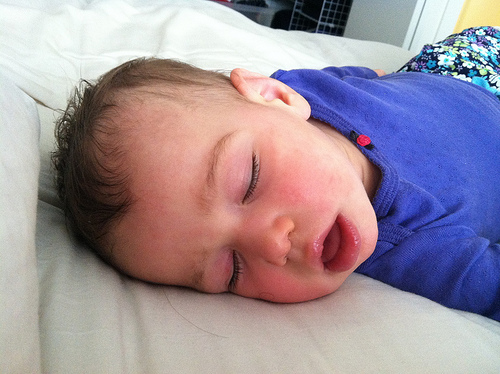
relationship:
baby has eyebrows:
[52, 24, 498, 296] [181, 122, 233, 299]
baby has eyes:
[52, 24, 498, 296] [217, 137, 266, 306]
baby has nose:
[52, 24, 498, 296] [248, 218, 299, 264]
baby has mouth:
[52, 24, 498, 296] [307, 200, 361, 282]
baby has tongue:
[52, 24, 498, 296] [323, 229, 344, 264]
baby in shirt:
[52, 24, 498, 296] [276, 44, 490, 311]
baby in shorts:
[52, 24, 498, 296] [398, 16, 499, 96]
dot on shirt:
[352, 129, 374, 151] [276, 44, 490, 311]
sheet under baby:
[0, 2, 463, 371] [52, 24, 498, 296]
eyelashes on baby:
[230, 149, 261, 302] [52, 24, 498, 296]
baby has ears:
[52, 24, 498, 296] [227, 61, 327, 120]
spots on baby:
[132, 102, 171, 149] [52, 24, 498, 296]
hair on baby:
[50, 50, 183, 274] [52, 24, 498, 296]